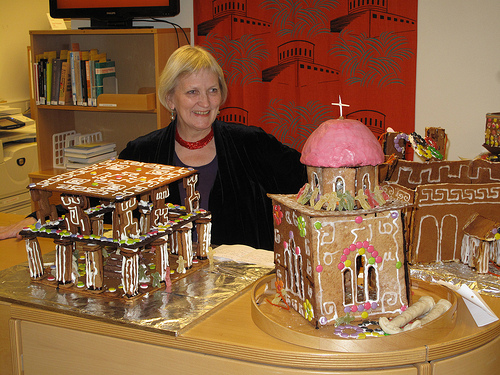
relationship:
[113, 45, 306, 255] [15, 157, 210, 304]
woman behind house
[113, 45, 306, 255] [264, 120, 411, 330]
woman behind house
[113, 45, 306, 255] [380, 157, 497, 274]
woman behind house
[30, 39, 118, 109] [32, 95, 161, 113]
books is on shelf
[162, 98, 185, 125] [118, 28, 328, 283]
earring is on woman